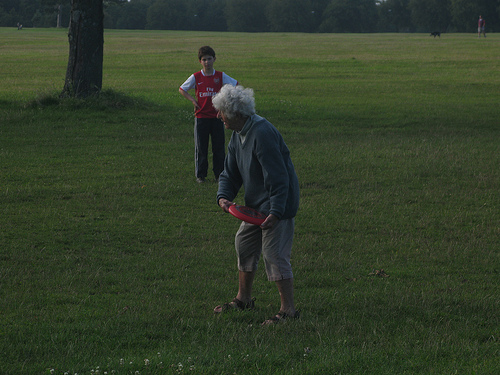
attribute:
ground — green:
[1, 24, 492, 374]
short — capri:
[228, 213, 301, 284]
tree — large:
[58, 1, 111, 101]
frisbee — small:
[223, 203, 268, 229]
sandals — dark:
[207, 294, 302, 333]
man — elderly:
[203, 82, 310, 326]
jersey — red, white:
[175, 71, 242, 122]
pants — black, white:
[191, 115, 227, 178]